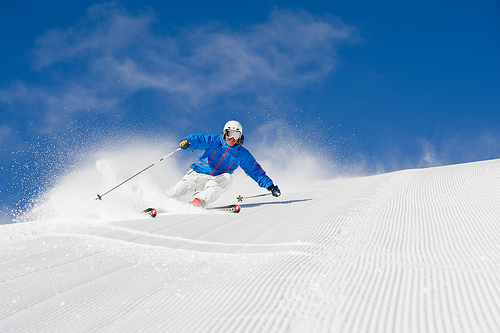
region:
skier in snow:
[124, 121, 278, 219]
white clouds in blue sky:
[331, 65, 403, 106]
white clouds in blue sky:
[387, 61, 454, 125]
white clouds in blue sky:
[270, 29, 330, 83]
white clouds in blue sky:
[140, 43, 204, 87]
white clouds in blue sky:
[227, 11, 292, 66]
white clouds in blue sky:
[94, 56, 136, 101]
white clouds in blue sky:
[4, 71, 71, 109]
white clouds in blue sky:
[45, 129, 107, 176]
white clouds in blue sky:
[72, 33, 150, 98]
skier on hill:
[107, 118, 291, 225]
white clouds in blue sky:
[15, 29, 63, 76]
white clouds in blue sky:
[355, 51, 417, 85]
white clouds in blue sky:
[275, 43, 300, 73]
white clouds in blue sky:
[174, 49, 224, 96]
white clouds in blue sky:
[81, 65, 115, 99]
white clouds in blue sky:
[130, 21, 182, 65]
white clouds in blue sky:
[54, 45, 104, 100]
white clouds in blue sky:
[32, 79, 64, 130]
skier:
[134, 103, 311, 253]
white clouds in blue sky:
[364, 61, 426, 111]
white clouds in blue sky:
[318, 29, 359, 80]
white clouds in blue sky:
[272, 86, 326, 144]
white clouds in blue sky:
[352, 23, 432, 100]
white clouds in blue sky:
[402, 15, 479, 79]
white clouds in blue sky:
[265, 29, 363, 110]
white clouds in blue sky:
[172, 35, 230, 80]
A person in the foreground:
[86, 110, 291, 236]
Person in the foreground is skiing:
[82, 96, 292, 241]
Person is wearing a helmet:
[214, 114, 248, 155]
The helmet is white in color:
[214, 116, 249, 151]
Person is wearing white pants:
[153, 162, 239, 221]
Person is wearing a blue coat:
[183, 123, 277, 203]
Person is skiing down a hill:
[84, 115, 302, 225]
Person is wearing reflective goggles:
[224, 124, 243, 144]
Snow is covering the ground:
[1, 155, 495, 330]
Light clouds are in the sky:
[1, 5, 407, 174]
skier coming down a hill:
[95, 119, 283, 219]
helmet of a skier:
[222, 118, 242, 131]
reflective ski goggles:
[224, 129, 241, 141]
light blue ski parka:
[178, 132, 275, 189]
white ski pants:
[164, 167, 235, 204]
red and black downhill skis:
[137, 204, 239, 217]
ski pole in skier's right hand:
[91, 137, 188, 202]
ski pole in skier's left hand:
[235, 184, 281, 201]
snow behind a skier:
[6, 125, 177, 219]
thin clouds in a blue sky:
[29, 1, 364, 111]